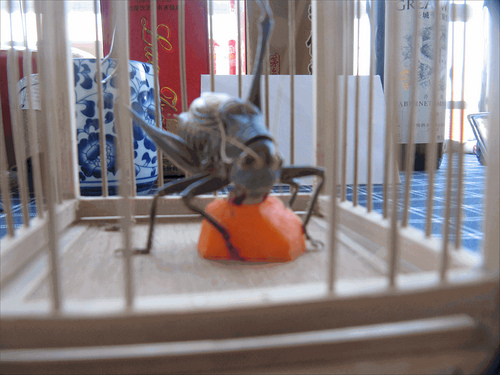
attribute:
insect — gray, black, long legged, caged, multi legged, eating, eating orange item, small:
[128, 85, 326, 192]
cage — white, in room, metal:
[257, 30, 420, 56]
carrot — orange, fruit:
[209, 210, 318, 253]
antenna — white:
[209, 110, 281, 177]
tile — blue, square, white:
[434, 177, 480, 219]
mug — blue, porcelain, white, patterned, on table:
[75, 89, 101, 160]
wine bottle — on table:
[420, 147, 427, 166]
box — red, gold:
[98, 0, 222, 153]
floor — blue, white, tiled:
[424, 181, 477, 228]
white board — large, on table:
[203, 74, 385, 164]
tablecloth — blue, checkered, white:
[451, 227, 470, 241]